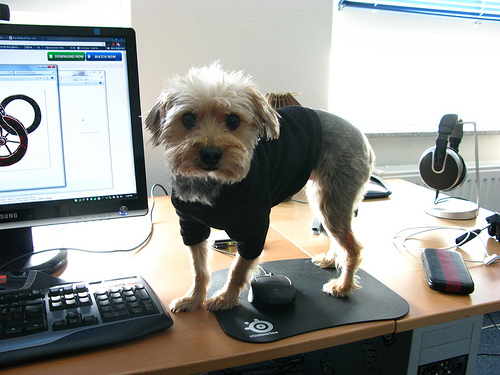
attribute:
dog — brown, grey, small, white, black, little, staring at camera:
[145, 64, 376, 314]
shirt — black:
[172, 107, 321, 259]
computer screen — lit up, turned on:
[0, 35, 137, 204]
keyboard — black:
[0, 272, 174, 364]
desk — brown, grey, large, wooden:
[0, 177, 499, 374]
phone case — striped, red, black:
[422, 247, 475, 295]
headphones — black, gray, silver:
[421, 115, 467, 192]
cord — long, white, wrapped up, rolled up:
[394, 224, 499, 266]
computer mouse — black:
[247, 272, 296, 314]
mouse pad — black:
[205, 257, 409, 343]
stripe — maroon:
[436, 248, 463, 292]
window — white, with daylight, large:
[326, 1, 499, 167]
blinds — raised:
[339, 2, 499, 22]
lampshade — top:
[265, 92, 301, 108]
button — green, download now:
[47, 52, 86, 60]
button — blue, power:
[86, 52, 124, 62]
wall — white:
[132, 2, 334, 198]